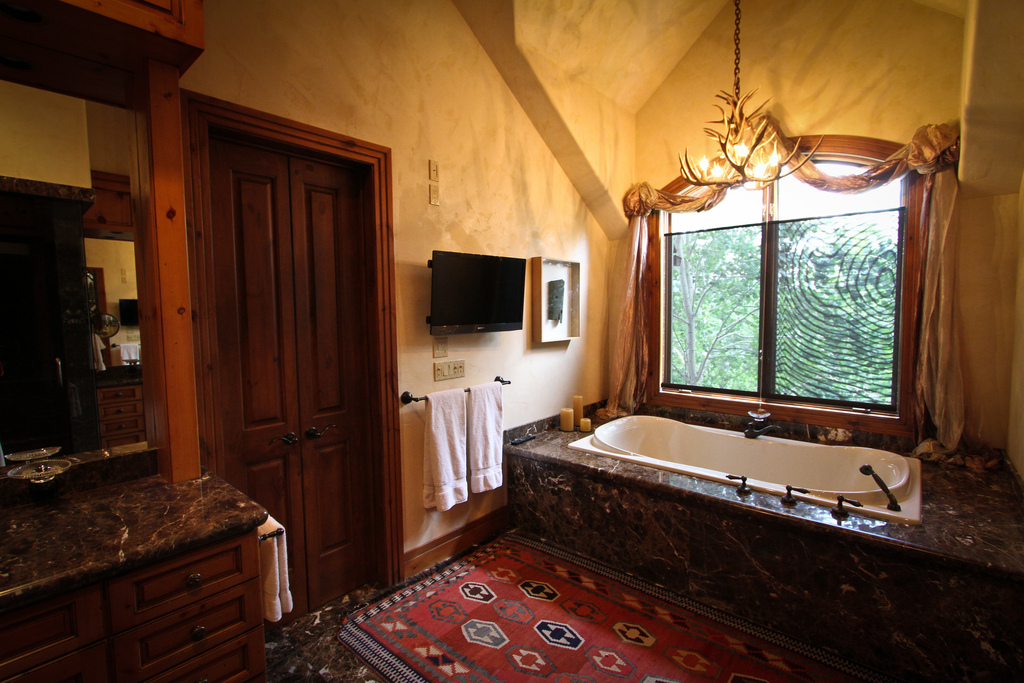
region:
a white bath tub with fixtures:
[572, 397, 946, 531]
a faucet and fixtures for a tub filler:
[723, 446, 917, 555]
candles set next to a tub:
[556, 379, 655, 447]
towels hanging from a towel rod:
[389, 363, 527, 516]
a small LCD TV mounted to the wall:
[404, 236, 538, 374]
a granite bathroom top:
[0, 452, 253, 627]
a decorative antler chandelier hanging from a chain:
[666, 16, 853, 213]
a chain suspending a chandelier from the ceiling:
[718, 4, 766, 188]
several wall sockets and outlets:
[417, 331, 484, 393]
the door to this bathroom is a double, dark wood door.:
[183, 94, 399, 614]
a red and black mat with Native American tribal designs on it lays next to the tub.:
[347, 535, 873, 679]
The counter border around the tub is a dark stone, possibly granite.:
[502, 402, 1016, 671]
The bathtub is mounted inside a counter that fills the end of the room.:
[566, 413, 934, 519]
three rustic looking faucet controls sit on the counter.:
[729, 471, 862, 519]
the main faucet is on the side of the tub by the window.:
[742, 408, 794, 440]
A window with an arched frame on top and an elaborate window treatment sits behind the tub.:
[618, 135, 969, 453]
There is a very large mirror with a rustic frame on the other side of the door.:
[10, 0, 198, 487]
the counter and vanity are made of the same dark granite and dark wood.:
[3, 481, 269, 678]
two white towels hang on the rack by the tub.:
[429, 382, 509, 512]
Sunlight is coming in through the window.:
[318, 578, 345, 582]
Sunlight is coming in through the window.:
[447, 572, 454, 579]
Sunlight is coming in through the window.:
[535, 484, 552, 489]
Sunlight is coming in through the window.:
[606, 387, 614, 392]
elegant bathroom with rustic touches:
[11, 16, 1001, 666]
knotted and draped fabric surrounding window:
[617, 103, 972, 462]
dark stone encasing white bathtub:
[504, 387, 1014, 667]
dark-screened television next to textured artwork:
[427, 245, 584, 348]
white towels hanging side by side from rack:
[392, 370, 516, 514]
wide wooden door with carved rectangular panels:
[174, 83, 402, 616]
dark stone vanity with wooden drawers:
[6, 469, 270, 670]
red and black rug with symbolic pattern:
[339, 529, 774, 673]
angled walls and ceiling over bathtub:
[156, 10, 1011, 538]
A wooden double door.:
[197, 111, 420, 608]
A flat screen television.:
[416, 263, 531, 334]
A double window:
[659, 233, 906, 421]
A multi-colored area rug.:
[355, 541, 744, 679]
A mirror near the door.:
[7, 94, 143, 494]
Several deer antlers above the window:
[665, 116, 799, 196]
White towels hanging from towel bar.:
[421, 402, 507, 529]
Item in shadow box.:
[539, 240, 582, 348]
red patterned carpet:
[352, 522, 937, 679]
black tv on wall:
[408, 216, 532, 346]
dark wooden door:
[191, 98, 441, 614]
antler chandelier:
[671, 75, 808, 225]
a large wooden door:
[166, 143, 452, 543]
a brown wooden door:
[143, 176, 385, 486]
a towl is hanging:
[433, 363, 462, 506]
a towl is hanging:
[450, 380, 476, 447]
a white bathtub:
[637, 424, 853, 555]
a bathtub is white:
[699, 360, 947, 591]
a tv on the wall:
[406, 199, 569, 351]